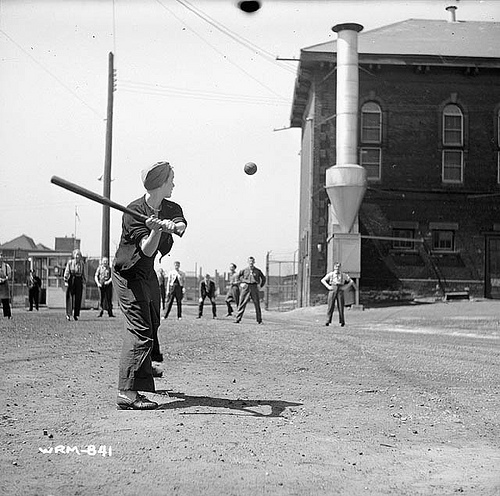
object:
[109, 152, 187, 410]
boy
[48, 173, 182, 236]
bat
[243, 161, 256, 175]
ball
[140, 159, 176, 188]
cap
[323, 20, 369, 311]
pipe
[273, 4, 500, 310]
building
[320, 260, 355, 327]
man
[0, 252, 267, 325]
men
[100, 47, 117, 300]
pole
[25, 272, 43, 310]
police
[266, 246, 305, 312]
gate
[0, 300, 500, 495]
yard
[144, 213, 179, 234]
hands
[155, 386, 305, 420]
shadow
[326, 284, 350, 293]
hands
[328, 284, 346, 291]
hips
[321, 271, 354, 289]
shirt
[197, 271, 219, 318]
person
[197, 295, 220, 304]
hands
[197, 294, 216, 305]
knees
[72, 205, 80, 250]
flag pole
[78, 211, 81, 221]
flag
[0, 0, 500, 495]
photograph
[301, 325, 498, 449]
tracks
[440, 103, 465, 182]
windows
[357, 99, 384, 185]
windows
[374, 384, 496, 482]
dirt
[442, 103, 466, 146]
window